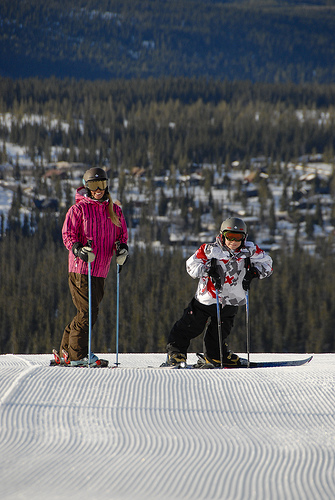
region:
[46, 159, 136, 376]
woman on some skis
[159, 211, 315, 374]
a boy on some skis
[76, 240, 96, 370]
blue metal ski pole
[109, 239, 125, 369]
blue metal ski pole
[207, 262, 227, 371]
blue and black ski pole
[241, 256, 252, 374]
blue and black ski pole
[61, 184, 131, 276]
pink and black jacket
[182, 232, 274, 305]
large white jacket with red and grey accents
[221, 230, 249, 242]
a pair of goggles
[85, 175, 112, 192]
pair of goggles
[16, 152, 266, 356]
2 skiers on the slopes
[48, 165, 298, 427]
a mom and son skiing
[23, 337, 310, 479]
neat lines in the snow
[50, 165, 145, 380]
she is wearing a pink ski coat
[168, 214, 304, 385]
he is wearing a white and red ski coat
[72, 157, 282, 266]
both skiiers are wearing helmets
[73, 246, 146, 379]
blue ski poles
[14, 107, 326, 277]
houses in the black ground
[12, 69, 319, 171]
lots of trees on the horizon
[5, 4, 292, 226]
this mountain is big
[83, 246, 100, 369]
a blue and grey ski pole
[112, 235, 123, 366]
a blue and grey ski pole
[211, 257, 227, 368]
a blue and grey ski pole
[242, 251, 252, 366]
a blue and grey ski pole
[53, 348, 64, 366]
red and blue binding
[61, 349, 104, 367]
red and blue binding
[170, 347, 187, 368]
a black and yellow boot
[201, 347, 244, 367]
a black and yellow boot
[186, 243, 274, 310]
a white red and grey winter coat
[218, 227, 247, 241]
orange ski goggles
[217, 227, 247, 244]
A pair of ski goggles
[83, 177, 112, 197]
A pair of ski goggles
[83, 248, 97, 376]
a blue ski pole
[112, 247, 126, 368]
a blue ski pole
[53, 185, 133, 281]
a pink ski jacket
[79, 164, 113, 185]
a black helmet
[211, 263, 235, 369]
a ski pole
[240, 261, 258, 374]
a ski pole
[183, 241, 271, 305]
a white and red ski jacket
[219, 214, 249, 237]
a black helmet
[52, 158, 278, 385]
a woman and a kid in top of a hill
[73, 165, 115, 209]
helmet is brown with big googles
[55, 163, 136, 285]
woman wears a pink and black jacket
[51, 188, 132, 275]
pink jacket has black stripes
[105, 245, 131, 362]
snow pole on right hand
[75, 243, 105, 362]
snow pole on left hand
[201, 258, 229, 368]
snow pole on left hand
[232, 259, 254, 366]
snow pole on right hand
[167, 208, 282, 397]
child wears a winter coat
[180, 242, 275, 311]
winter coat is white and red